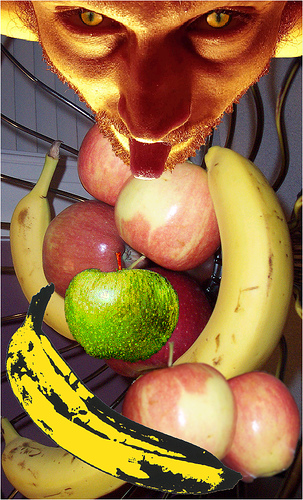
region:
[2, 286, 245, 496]
Cartoon banana, black and yellow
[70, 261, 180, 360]
Granny Smith Apple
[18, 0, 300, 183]
Man with his tongue out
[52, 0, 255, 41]
Man with cat's eyes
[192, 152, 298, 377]
Upright yellow banana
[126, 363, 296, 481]
A pair of apples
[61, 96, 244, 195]
Stubble on a man's face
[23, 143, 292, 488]
group of assorted fruits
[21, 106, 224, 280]
Red apples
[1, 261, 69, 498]
Several bananas, one of them is photoshopped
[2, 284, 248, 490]
a graphic of a banana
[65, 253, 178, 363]
a computer graphic of a green apple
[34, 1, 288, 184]
a man's face with his tongue sticking out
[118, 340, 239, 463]
a red and yellow apple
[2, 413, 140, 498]
a yellow banana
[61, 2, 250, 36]
yellow eyes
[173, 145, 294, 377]
a yellow banana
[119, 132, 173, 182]
a tongue sticking out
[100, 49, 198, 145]
a nose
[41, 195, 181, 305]
a red apple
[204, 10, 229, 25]
Man with yellow eyes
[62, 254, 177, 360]
Green apple with red stem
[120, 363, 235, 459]
Fresh red apple with green stem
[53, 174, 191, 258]
Group of red apples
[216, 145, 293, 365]
Yellow banana with small abrasions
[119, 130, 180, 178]
Man sticking tongue out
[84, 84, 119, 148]
One side of dark brown beard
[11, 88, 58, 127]
Grey vertical wall paneling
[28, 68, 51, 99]
Black metal bar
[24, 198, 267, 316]
Group of arranged fruit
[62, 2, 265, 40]
The person has yellow eyes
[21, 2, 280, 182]
The person is sticking out their tongue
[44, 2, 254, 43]
The mans pupils are cat like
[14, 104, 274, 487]
A pile of fruit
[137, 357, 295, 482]
Two red and yellow apples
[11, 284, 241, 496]
A drawing of a banana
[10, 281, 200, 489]
The banana is yellow and black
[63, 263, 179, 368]
The apple is green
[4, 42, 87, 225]
A shiny silver fruit holder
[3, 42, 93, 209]
The wall has white panels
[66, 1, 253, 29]
two eyes of a person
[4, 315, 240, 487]
a banana placed in front of apple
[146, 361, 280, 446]
two apples placed behind banana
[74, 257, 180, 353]
green apple placed in between fruits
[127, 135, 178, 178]
tongue of a person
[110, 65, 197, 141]
nose of a person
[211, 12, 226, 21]
pupil of a eye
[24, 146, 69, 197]
top stem of banana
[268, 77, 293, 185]
iron stand of fruits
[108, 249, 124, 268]
top portion of apple